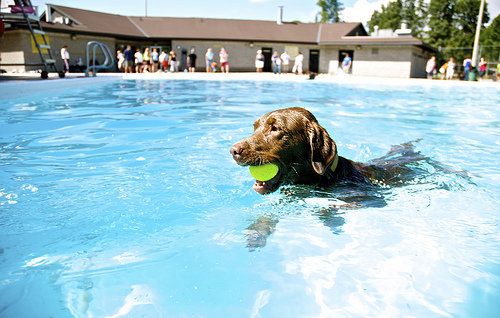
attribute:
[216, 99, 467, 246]
dog — swimming, big, brown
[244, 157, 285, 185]
ball — round, green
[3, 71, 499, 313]
water — deep, blue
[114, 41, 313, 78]
people — standing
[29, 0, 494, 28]
building — white, brown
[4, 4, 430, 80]
sky — white, blue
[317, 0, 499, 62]
trees — green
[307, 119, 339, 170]
ear — is folded